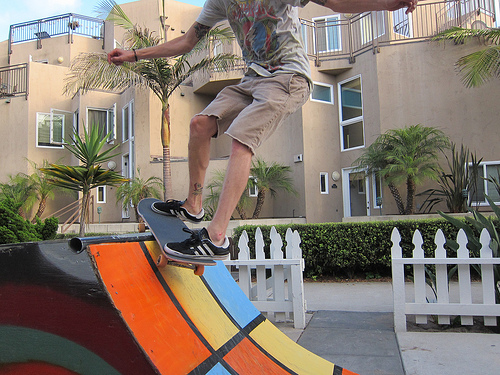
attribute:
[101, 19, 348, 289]
man — skateboarding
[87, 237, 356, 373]
ramp — yellow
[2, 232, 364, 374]
jump — yellow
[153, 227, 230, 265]
sneakers — black and white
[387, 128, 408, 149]
leaf — green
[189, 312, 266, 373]
line — black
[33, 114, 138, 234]
trees — palm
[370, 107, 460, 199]
leaf — green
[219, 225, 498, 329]
fence — white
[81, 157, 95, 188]
leaf — green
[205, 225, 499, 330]
picket fence — white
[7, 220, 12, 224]
leaf — green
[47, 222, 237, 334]
ramp — orange-colored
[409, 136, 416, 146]
leaf — green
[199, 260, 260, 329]
ramp — blue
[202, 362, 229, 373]
ramp — blue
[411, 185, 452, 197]
leaf — green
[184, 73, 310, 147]
shorts — tan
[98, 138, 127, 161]
leaf — green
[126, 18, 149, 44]
leaf — green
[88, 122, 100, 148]
leaf — green